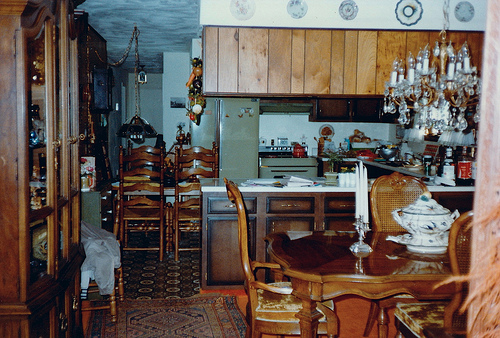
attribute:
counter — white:
[212, 182, 220, 187]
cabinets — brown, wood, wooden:
[313, 204, 335, 212]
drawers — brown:
[250, 203, 346, 213]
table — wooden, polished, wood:
[308, 246, 334, 283]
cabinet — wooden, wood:
[17, 33, 71, 244]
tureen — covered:
[412, 201, 439, 238]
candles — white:
[354, 169, 368, 244]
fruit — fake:
[191, 64, 201, 132]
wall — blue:
[214, 55, 240, 79]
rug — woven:
[185, 307, 223, 331]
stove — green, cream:
[271, 157, 308, 172]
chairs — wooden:
[130, 153, 197, 197]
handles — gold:
[286, 203, 298, 208]